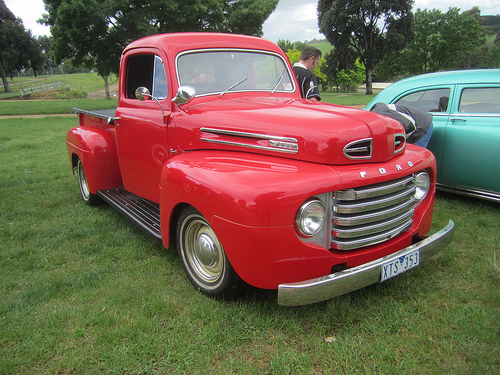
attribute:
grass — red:
[1, 74, 497, 373]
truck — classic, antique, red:
[68, 32, 454, 307]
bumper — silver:
[277, 213, 456, 319]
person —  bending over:
[369, 103, 435, 148]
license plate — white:
[379, 247, 421, 282]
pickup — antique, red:
[60, 26, 460, 316]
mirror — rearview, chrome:
[132, 79, 167, 121]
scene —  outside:
[61, 30, 499, 352]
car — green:
[362, 63, 498, 208]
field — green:
[2, 97, 496, 372]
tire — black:
[172, 210, 233, 300]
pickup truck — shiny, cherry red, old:
[63, 28, 456, 308]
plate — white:
[376, 248, 426, 284]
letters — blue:
[377, 250, 420, 277]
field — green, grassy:
[0, 120, 497, 368]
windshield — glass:
[134, 40, 254, 100]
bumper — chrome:
[273, 220, 466, 306]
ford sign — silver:
[354, 158, 411, 177]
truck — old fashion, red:
[59, 19, 464, 315]